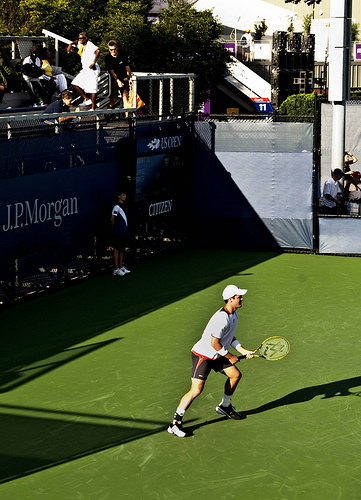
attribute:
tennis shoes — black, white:
[164, 394, 266, 427]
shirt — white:
[110, 201, 129, 234]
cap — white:
[219, 283, 247, 300]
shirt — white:
[74, 38, 101, 69]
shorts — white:
[69, 68, 100, 95]